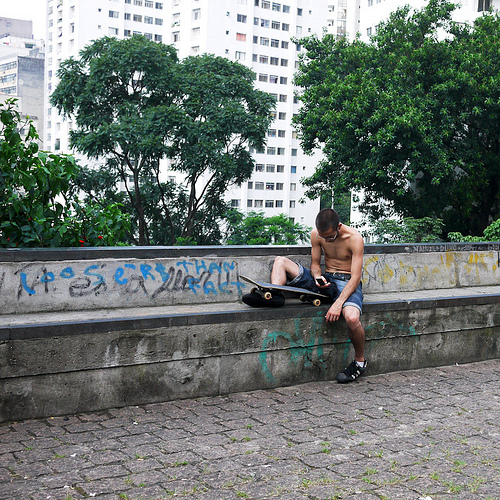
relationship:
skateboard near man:
[238, 274, 326, 308] [244, 208, 377, 384]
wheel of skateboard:
[262, 289, 274, 303] [238, 274, 326, 308]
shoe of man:
[240, 287, 287, 308] [244, 208, 377, 384]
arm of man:
[322, 237, 366, 325] [244, 208, 377, 384]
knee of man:
[343, 313, 361, 330] [244, 208, 377, 384]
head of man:
[313, 207, 344, 243] [244, 208, 377, 384]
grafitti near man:
[5, 256, 238, 309] [244, 208, 377, 384]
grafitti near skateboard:
[5, 256, 238, 309] [238, 274, 326, 308]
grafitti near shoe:
[5, 256, 238, 309] [240, 287, 287, 308]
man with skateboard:
[244, 208, 377, 384] [238, 274, 326, 308]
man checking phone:
[244, 208, 377, 384] [314, 276, 326, 288]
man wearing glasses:
[244, 208, 377, 384] [316, 231, 339, 243]